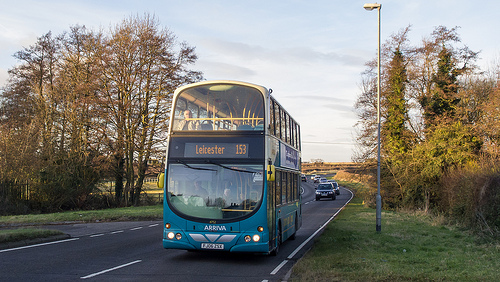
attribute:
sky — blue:
[248, 20, 289, 52]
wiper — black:
[180, 157, 218, 172]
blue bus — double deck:
[161, 80, 303, 257]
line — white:
[81, 255, 142, 280]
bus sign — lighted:
[190, 138, 248, 160]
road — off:
[0, 217, 162, 239]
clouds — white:
[298, 50, 355, 86]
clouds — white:
[191, 39, 393, 124]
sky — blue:
[0, 1, 499, 163]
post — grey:
[360, 1, 413, 243]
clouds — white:
[245, 26, 382, 137]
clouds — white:
[296, 38, 371, 118]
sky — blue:
[23, 10, 488, 153]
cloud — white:
[193, 22, 314, 93]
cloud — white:
[306, 77, 348, 130]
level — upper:
[158, 61, 302, 159]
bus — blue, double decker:
[165, 83, 305, 257]